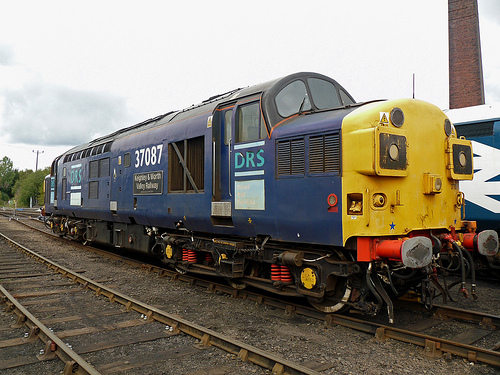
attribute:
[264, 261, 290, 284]
springs — metal, red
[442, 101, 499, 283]
white train — blue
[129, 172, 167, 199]
sign — black, white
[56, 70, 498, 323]
engine — yellow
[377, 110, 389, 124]
sticker — white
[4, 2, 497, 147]
sky — cloudy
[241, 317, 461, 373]
rocks — small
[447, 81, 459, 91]
brick — tall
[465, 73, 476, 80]
brick — tall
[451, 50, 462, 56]
brick — tall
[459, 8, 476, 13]
brick — tall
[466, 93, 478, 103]
brick — tall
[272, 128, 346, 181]
grates — metal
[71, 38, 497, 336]
train — blue, yellow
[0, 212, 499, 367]
tracks — old, metal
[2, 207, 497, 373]
train tracks — rusty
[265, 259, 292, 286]
metal spring — red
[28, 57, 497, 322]
train — yellow, blue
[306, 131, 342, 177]
grate — dark, metal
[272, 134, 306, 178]
grate — dark, metal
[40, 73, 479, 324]
engine car — dark blue, yellow